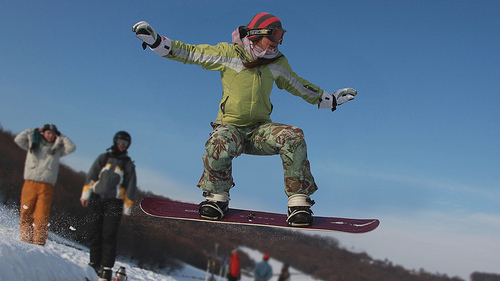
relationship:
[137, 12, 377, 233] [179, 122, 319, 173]
person with knees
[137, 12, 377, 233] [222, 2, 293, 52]
person with a helmet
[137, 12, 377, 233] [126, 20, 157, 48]
person with glove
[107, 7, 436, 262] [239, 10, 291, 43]
person with a helmet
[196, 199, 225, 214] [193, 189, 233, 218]
bindings are on snowboarding boots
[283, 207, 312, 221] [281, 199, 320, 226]
bindings are on snowboarding boots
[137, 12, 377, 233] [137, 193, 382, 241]
person jumping on snowboard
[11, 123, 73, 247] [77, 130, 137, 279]
person standing next to person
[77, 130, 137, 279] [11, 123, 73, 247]
person standing next to person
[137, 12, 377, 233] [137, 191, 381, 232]
person standing on board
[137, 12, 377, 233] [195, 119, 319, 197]
person wearing pants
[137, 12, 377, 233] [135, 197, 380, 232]
person on board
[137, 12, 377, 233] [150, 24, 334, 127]
person wearing jacket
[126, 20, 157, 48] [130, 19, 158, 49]
glove covering hand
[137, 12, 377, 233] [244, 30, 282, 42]
person wearing goggles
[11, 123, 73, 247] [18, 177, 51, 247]
person wearing pants